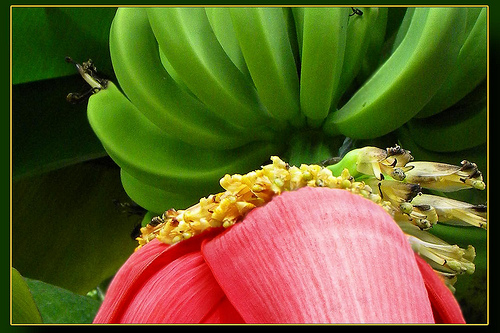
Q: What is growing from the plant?
A: A flower.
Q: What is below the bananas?
A: A flower.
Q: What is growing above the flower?
A: Bananas.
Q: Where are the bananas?
A: On the tree.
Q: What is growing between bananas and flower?
A: Sprouts.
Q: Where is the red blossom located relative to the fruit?
A: Below the fruit.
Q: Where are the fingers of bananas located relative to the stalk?
A: Around the stalk.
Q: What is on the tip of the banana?
A: A dying blossom.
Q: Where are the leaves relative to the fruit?
A: Behind the fruit.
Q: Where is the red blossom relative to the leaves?
A: In front of them.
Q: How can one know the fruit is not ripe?
A: Fruit is still green.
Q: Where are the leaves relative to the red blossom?
A: Behind it.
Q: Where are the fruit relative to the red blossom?
A: Above it.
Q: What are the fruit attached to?
A: The stalk.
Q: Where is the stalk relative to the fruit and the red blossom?
A: Between them.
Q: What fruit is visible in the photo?
A: Bananas.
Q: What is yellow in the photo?
A: Seeds.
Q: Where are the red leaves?
A: On plant.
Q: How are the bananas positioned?
A: In a bunch.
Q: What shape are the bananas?
A: Curved.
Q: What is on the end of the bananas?
A: Stems.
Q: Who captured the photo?
A: A photographer.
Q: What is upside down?
A: Bananas.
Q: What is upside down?
A: Bananas.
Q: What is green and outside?
A: Bananas.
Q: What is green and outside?
A: Bananas.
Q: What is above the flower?
A: Bananas.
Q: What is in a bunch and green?
A: Bananas.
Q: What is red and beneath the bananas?
A: Leaves.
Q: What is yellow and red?
A: Leaves.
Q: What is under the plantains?
A: A flower.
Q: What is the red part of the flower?
A: Petals.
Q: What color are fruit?
A: Green.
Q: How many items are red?
A: One.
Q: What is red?
A: Flowers.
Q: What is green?
A: Fruit.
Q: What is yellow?
A: Pollen.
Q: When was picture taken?
A: Daytime.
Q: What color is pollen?
A: Yellow.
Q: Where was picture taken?
A: Close to plant.